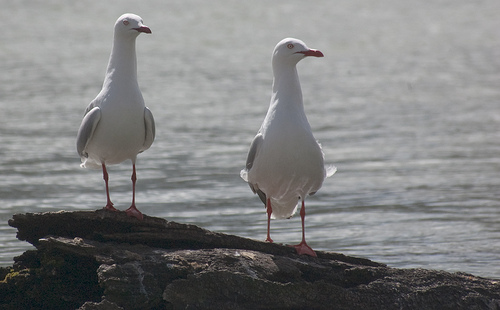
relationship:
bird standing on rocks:
[240, 31, 330, 261] [3, 209, 497, 308]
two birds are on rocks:
[77, 11, 339, 262] [3, 209, 497, 308]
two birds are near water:
[77, 11, 339, 262] [1, 1, 499, 276]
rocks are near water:
[3, 209, 497, 308] [1, 1, 499, 276]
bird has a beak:
[240, 31, 330, 261] [300, 45, 326, 60]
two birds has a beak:
[76, 12, 157, 221] [133, 24, 153, 37]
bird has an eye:
[240, 31, 330, 261] [284, 40, 297, 53]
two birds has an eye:
[76, 12, 157, 221] [121, 17, 130, 30]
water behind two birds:
[1, 1, 499, 276] [77, 11, 339, 262]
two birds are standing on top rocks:
[77, 11, 339, 262] [3, 209, 497, 308]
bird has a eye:
[240, 31, 330, 261] [284, 40, 297, 53]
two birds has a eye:
[76, 12, 157, 221] [121, 17, 130, 30]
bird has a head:
[240, 31, 330, 261] [271, 34, 325, 68]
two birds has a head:
[76, 12, 157, 221] [113, 10, 153, 44]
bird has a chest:
[240, 31, 330, 261] [267, 124, 315, 167]